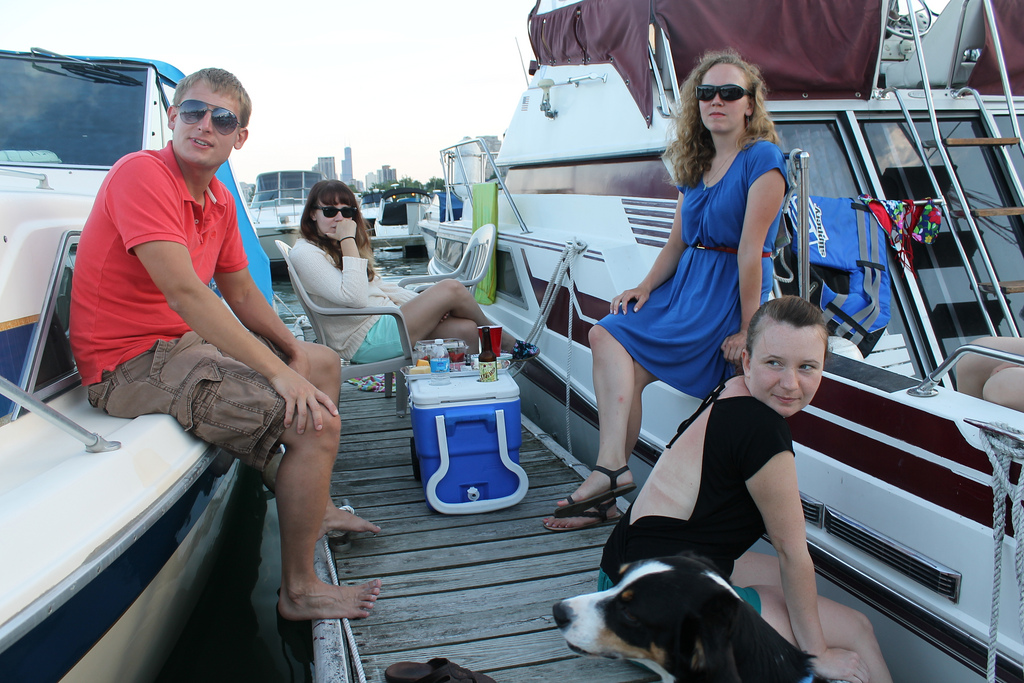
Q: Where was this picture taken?
A: On a boat.